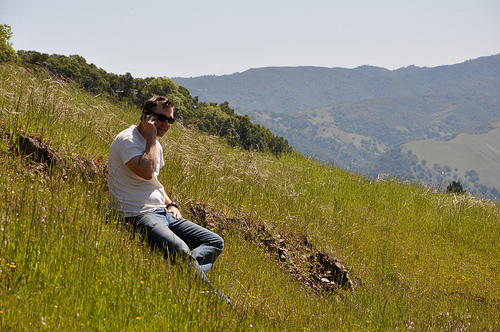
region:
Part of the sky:
[213, 17, 274, 39]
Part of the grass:
[71, 252, 120, 295]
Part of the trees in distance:
[78, 64, 92, 86]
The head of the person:
[138, 92, 175, 138]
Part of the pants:
[152, 216, 160, 227]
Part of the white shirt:
[118, 178, 132, 194]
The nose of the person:
[161, 114, 171, 129]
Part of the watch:
[167, 201, 176, 206]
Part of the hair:
[143, 99, 152, 106]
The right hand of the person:
[138, 109, 160, 139]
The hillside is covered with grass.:
[1, 35, 497, 330]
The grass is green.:
[0, 43, 499, 330]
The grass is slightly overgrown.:
[2, 52, 498, 329]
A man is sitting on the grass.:
[1, 41, 497, 330]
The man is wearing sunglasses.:
[1, 38, 499, 330]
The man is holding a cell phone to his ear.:
[3, 51, 498, 330]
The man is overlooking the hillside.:
[1, 47, 498, 330]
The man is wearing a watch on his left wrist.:
[1, 56, 493, 328]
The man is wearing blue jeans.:
[84, 68, 250, 316]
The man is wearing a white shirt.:
[93, 66, 263, 319]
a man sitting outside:
[62, 47, 349, 329]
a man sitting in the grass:
[57, 101, 211, 306]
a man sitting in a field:
[77, 63, 262, 330]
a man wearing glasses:
[111, 53, 251, 325]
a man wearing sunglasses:
[49, 34, 260, 327]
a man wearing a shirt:
[89, 79, 279, 330]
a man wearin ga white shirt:
[87, 71, 282, 288]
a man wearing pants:
[62, 81, 276, 328]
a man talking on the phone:
[108, 78, 336, 327]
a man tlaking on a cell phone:
[104, 91, 222, 268]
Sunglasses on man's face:
[138, 112, 173, 125]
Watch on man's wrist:
[163, 199, 180, 211]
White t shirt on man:
[107, 123, 167, 215]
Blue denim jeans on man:
[123, 209, 226, 306]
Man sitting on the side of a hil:
[106, 94, 251, 319]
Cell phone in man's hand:
[137, 110, 157, 129]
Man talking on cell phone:
[110, 97, 243, 306]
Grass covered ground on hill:
[0, 63, 496, 330]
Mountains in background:
[153, 49, 494, 196]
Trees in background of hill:
[1, 24, 297, 155]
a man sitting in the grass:
[103, 94, 263, 312]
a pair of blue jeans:
[126, 210, 237, 299]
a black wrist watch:
[166, 198, 178, 209]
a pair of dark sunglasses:
[147, 109, 177, 124]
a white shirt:
[106, 120, 175, 215]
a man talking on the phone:
[137, 97, 177, 137]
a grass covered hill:
[1, 48, 498, 329]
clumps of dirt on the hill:
[17, 128, 381, 296]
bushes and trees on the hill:
[34, 47, 289, 159]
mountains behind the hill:
[172, 56, 498, 200]